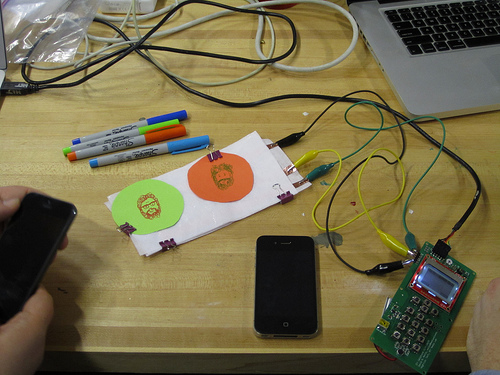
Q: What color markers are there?
A: Blue, green and orange.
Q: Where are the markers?
A: On the table.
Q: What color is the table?
A: Brown.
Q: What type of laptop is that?
A: Mac.